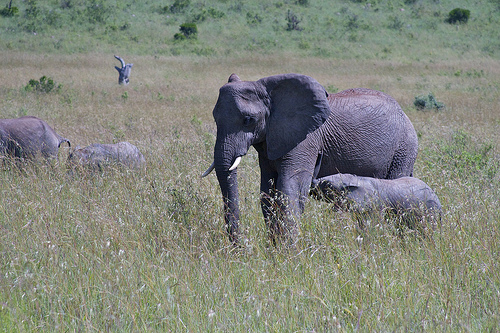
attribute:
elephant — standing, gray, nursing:
[203, 73, 421, 250]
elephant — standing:
[316, 148, 444, 231]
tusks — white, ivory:
[230, 154, 243, 173]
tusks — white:
[199, 164, 217, 180]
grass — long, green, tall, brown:
[167, 271, 169, 332]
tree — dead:
[115, 55, 133, 86]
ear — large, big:
[270, 76, 331, 157]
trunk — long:
[211, 154, 241, 244]